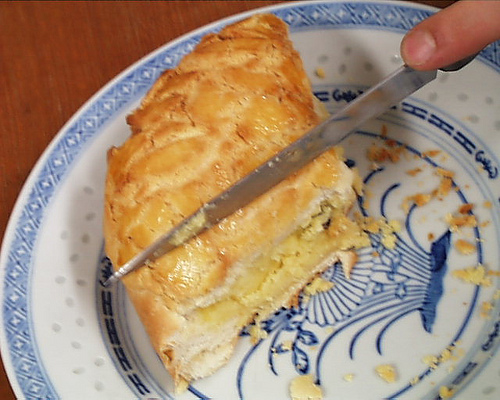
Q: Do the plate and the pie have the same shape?
A: Yes, both the plate and the pie are round.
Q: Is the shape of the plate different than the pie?
A: No, both the plate and the pie are round.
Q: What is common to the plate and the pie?
A: The shape, both the plate and the pie are round.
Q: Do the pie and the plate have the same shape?
A: Yes, both the pie and the plate are round.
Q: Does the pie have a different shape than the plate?
A: No, both the pie and the plate are round.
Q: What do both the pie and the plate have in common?
A: The shape, both the pie and the plate are round.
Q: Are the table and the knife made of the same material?
A: No, the table is made of wood and the knife is made of metal.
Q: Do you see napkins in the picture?
A: No, there are no napkins.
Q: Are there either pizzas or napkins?
A: No, there are no napkins or pizzas.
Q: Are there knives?
A: Yes, there is a knife.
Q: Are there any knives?
A: Yes, there is a knife.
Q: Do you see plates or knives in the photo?
A: Yes, there is a knife.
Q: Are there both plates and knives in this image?
A: Yes, there are both a knife and plates.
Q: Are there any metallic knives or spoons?
A: Yes, there is a metal knife.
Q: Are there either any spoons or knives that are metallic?
A: Yes, the knife is metallic.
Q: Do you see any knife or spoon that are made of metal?
A: Yes, the knife is made of metal.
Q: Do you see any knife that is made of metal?
A: Yes, there is a knife that is made of metal.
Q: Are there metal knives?
A: Yes, there is a knife that is made of metal.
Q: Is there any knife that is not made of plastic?
A: Yes, there is a knife that is made of metal.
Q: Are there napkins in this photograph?
A: No, there are no napkins.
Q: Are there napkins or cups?
A: No, there are no napkins or cups.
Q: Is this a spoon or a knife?
A: This is a knife.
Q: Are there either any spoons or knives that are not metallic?
A: No, there is a knife but it is metallic.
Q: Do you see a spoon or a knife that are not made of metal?
A: No, there is a knife but it is made of metal.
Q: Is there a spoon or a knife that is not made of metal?
A: No, there is a knife but it is made of metal.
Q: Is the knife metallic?
A: Yes, the knife is metallic.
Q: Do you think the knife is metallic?
A: Yes, the knife is metallic.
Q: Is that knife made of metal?
A: Yes, the knife is made of metal.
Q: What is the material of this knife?
A: The knife is made of metal.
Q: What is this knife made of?
A: The knife is made of metal.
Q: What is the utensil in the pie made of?
A: The knife is made of metal.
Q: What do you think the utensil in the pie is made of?
A: The knife is made of metal.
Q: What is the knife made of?
A: The knife is made of metal.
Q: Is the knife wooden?
A: No, the knife is metallic.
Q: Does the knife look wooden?
A: No, the knife is metallic.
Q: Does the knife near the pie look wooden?
A: No, the knife is metallic.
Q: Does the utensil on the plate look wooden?
A: No, the knife is metallic.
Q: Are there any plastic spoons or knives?
A: No, there is a knife but it is metallic.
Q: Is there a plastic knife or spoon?
A: No, there is a knife but it is metallic.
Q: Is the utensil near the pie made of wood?
A: No, the knife is made of metal.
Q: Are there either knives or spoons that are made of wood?
A: No, there is a knife but it is made of metal.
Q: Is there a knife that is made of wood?
A: No, there is a knife but it is made of metal.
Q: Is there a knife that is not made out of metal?
A: No, there is a knife but it is made of metal.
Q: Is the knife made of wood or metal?
A: The knife is made of metal.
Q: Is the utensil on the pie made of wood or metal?
A: The knife is made of metal.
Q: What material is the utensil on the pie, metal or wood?
A: The knife is made of metal.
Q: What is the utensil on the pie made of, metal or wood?
A: The knife is made of metal.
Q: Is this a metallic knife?
A: Yes, this is a metallic knife.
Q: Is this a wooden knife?
A: No, this is a metallic knife.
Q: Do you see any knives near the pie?
A: Yes, there is a knife near the pie.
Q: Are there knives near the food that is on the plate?
A: Yes, there is a knife near the pie.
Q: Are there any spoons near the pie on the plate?
A: No, there is a knife near the pie.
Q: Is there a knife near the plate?
A: Yes, there is a knife near the plate.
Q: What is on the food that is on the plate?
A: The knife is on the pie.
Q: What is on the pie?
A: The knife is on the pie.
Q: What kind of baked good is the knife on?
A: The knife is on the pie.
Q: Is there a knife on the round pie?
A: Yes, there is a knife on the pie.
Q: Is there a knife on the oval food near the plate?
A: Yes, there is a knife on the pie.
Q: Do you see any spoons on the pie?
A: No, there is a knife on the pie.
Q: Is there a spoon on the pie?
A: No, there is a knife on the pie.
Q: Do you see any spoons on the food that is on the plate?
A: No, there is a knife on the pie.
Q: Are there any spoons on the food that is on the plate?
A: No, there is a knife on the pie.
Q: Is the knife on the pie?
A: Yes, the knife is on the pie.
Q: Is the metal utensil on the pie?
A: Yes, the knife is on the pie.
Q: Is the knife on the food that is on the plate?
A: Yes, the knife is on the pie.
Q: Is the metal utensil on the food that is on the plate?
A: Yes, the knife is on the pie.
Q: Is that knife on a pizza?
A: No, the knife is on the pie.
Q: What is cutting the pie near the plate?
A: The knife is cutting the pie.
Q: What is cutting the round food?
A: The knife is cutting the pie.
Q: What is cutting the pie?
A: The knife is cutting the pie.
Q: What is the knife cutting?
A: The knife is cutting the pie.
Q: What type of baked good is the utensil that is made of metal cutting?
A: The knife is cutting the pie.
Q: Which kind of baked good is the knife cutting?
A: The knife is cutting the pie.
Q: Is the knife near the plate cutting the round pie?
A: Yes, the knife is cutting the pie.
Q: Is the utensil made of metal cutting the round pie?
A: Yes, the knife is cutting the pie.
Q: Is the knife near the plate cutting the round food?
A: Yes, the knife is cutting the pie.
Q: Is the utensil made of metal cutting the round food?
A: Yes, the knife is cutting the pie.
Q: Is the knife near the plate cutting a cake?
A: No, the knife is cutting the pie.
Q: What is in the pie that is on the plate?
A: The knife is in the pie.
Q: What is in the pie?
A: The knife is in the pie.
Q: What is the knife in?
A: The knife is in the pie.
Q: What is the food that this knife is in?
A: The food is a pie.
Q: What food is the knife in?
A: The knife is in the pie.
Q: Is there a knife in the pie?
A: Yes, there is a knife in the pie.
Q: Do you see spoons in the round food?
A: No, there is a knife in the pie.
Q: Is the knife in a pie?
A: Yes, the knife is in a pie.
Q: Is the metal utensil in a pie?
A: Yes, the knife is in a pie.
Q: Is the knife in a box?
A: No, the knife is in a pie.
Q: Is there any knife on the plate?
A: Yes, there is a knife on the plate.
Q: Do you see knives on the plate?
A: Yes, there is a knife on the plate.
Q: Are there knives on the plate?
A: Yes, there is a knife on the plate.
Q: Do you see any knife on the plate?
A: Yes, there is a knife on the plate.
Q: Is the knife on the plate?
A: Yes, the knife is on the plate.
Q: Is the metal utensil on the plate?
A: Yes, the knife is on the plate.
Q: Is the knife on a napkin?
A: No, the knife is on the plate.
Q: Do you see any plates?
A: Yes, there is a plate.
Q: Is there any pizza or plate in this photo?
A: Yes, there is a plate.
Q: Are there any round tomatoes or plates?
A: Yes, there is a round plate.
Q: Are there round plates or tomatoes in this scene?
A: Yes, there is a round plate.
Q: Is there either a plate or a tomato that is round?
A: Yes, the plate is round.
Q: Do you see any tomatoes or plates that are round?
A: Yes, the plate is round.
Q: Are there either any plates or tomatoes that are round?
A: Yes, the plate is round.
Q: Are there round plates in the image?
A: Yes, there is a round plate.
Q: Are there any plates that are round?
A: Yes, there is a plate that is round.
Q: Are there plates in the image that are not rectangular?
A: Yes, there is a round plate.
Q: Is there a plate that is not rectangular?
A: Yes, there is a round plate.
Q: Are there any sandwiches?
A: No, there are no sandwiches.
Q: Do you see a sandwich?
A: No, there are no sandwiches.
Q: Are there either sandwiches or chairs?
A: No, there are no sandwiches or chairs.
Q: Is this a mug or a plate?
A: This is a plate.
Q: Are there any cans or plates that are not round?
A: No, there is a plate but it is round.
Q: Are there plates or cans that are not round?
A: No, there is a plate but it is round.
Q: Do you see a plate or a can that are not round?
A: No, there is a plate but it is round.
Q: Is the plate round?
A: Yes, the plate is round.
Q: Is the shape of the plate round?
A: Yes, the plate is round.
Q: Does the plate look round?
A: Yes, the plate is round.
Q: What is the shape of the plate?
A: The plate is round.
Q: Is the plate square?
A: No, the plate is round.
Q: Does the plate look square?
A: No, the plate is round.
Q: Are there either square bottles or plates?
A: No, there is a plate but it is round.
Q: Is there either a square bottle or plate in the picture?
A: No, there is a plate but it is round.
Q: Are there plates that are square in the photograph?
A: No, there is a plate but it is round.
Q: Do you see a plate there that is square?
A: No, there is a plate but it is round.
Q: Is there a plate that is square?
A: No, there is a plate but it is round.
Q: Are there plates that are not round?
A: No, there is a plate but it is round.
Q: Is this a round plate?
A: Yes, this is a round plate.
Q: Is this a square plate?
A: No, this is a round plate.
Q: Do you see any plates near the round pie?
A: Yes, there is a plate near the pie.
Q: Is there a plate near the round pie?
A: Yes, there is a plate near the pie.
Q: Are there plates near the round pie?
A: Yes, there is a plate near the pie.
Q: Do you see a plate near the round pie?
A: Yes, there is a plate near the pie.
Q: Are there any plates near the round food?
A: Yes, there is a plate near the pie.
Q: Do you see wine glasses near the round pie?
A: No, there is a plate near the pie.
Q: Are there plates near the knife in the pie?
A: Yes, there is a plate near the knife.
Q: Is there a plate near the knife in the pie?
A: Yes, there is a plate near the knife.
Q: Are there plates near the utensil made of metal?
A: Yes, there is a plate near the knife.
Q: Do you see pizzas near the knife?
A: No, there is a plate near the knife.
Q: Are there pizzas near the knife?
A: No, there is a plate near the knife.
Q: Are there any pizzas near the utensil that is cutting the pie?
A: No, there is a plate near the knife.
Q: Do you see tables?
A: Yes, there is a table.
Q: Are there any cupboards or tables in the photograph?
A: Yes, there is a table.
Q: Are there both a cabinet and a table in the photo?
A: No, there is a table but no cabinets.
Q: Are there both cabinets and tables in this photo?
A: No, there is a table but no cabinets.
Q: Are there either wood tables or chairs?
A: Yes, there is a wood table.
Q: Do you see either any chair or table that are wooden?
A: Yes, the table is wooden.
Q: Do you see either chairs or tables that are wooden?
A: Yes, the table is wooden.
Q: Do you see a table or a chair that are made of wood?
A: Yes, the table is made of wood.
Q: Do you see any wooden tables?
A: Yes, there is a wood table.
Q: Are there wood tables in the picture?
A: Yes, there is a wood table.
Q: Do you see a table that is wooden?
A: Yes, there is a wood table.